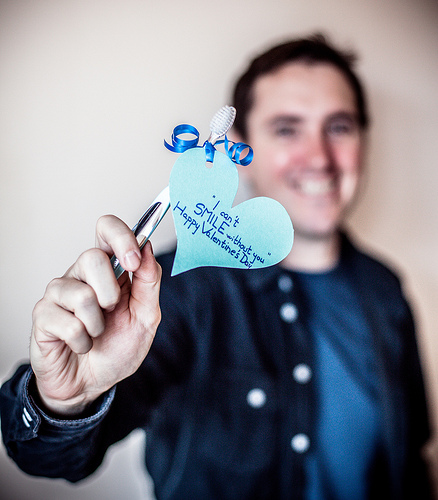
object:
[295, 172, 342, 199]
mouth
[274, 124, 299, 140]
eye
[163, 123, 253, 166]
ribbon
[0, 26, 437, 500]
man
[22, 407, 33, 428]
buttons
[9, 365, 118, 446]
cuff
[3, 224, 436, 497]
shirt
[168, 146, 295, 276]
tag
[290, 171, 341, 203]
smile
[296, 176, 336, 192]
teeth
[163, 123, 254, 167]
speaker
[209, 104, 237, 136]
head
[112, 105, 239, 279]
toothbrush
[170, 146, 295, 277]
heart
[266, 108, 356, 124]
eyebrows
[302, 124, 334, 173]
nose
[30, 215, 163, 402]
hand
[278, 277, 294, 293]
button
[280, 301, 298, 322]
button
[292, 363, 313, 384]
button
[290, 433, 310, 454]
button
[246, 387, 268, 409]
button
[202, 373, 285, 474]
pocket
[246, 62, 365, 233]
face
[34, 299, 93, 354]
finger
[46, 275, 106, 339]
finger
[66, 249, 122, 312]
finger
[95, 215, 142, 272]
finger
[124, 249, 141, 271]
fingernail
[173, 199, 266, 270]
note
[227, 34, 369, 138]
hair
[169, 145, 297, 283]
paper